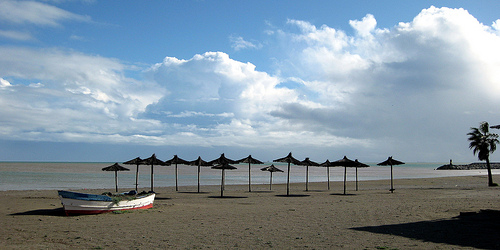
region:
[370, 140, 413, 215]
This is an umbrella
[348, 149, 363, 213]
This is an umbrella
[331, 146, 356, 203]
This is an umbrella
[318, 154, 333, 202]
This is an umbrella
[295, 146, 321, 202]
This is an umbrella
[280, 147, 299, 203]
This is an umbrella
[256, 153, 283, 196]
This is an umbrella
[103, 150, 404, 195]
Row of upright umbrellas on beach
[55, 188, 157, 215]
Small boat sitting on beach above water line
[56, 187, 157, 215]
Red, white, and blue boat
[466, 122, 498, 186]
Lone palm tree on sandy beach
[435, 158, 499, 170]
Rock headland with upright figure near tip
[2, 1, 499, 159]
Blue sky with many fluffy white clouds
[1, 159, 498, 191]
Expanse of iridescent ocean water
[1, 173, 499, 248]
Sandy gray beach with boat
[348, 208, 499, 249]
Shadow of structure outside of frame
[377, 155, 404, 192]
Single black-shaded umbrella on beach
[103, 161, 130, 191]
a black beach umbrella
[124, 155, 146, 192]
a black beach umbrella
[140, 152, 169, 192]
a black beach umbrella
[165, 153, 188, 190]
a black beach umbrella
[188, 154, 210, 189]
a black beach umbrella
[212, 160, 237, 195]
a black beach umbrella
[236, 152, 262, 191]
a black beach umbrella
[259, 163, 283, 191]
a black beach umbrella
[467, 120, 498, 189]
a large palm tree in distance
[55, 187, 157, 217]
a stranded blue white and red row boat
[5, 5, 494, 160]
blue sky with connected white clouds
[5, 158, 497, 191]
calm and flat gray ocean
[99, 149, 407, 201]
dark umbrellas standing in a row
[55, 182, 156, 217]
small red, white and blue boat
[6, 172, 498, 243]
flat brown sand with footprints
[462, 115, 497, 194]
palm tree growing in sand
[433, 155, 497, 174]
lighthouse on flat land jutting into ocean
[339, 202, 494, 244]
shadow pointing across the beach sand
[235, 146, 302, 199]
shorter umbrella in between two taller ones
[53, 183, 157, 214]
stripes painted across the rowboat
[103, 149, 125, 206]
LArge umbrella in the sand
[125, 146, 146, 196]
LArge umbrella in the sand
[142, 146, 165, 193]
LArge umbrella in the sand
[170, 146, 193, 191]
LArge umbrella in the sand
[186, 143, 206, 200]
LArge umbrella in the sand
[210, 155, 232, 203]
LArge umbrella in the sand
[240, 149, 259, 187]
LArge umbrella in the sand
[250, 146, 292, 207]
LArge umbrella in the sand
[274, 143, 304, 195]
LArge umbrella in the sand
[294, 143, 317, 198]
LArge umbrella in the sand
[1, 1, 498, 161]
Blue sky with big puffy white clouds.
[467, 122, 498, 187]
A palm tree.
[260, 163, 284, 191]
The smallest opened umbrella.